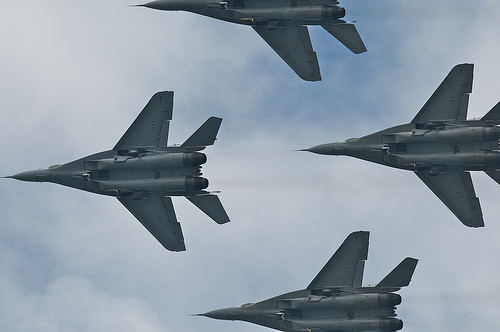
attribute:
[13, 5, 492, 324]
jets — flying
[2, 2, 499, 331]
sky — cloudy, blue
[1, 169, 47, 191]
nose — pointed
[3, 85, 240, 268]
jet — flying, gray, fighter, plane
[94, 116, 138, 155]
edges — curved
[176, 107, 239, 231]
tail — flared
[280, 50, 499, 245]
jet — following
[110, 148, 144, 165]
panels — open, rectangular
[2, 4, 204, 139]
cloud — white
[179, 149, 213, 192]
engines — black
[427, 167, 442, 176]
wheel — round, black